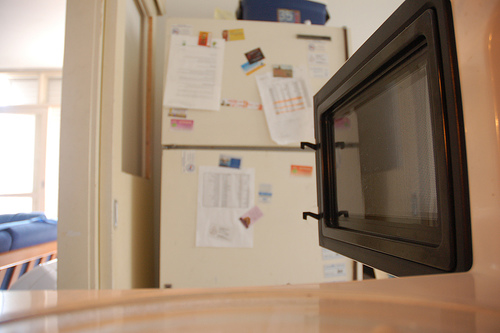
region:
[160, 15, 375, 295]
A refrigerator.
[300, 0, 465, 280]
The inside of the microwave door.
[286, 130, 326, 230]
Hooks that lock the door when it is closed.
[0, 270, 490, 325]
The glass dish.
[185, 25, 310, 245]
Various magnets are on the fridge.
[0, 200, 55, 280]
A couch.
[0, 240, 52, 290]
The couch has a wood frame.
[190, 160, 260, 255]
A piece of paper is attached to the fridge.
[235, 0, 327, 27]
A blue plastic tub.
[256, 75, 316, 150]
The paper has been highlighted.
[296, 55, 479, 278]
Black, opened door of the microwave.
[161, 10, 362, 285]
Beige colored refrigerator in the kitchen.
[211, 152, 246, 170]
Magnet on the refrigerator holding up a paper.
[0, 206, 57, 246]
Blue cushions on the couch.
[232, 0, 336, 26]
Object sitting on top of the fridge.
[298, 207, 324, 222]
Locking mechanism for the microwave door.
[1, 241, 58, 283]
Couch made of wood.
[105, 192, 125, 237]
Light switch on the wall.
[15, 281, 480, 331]
Round plate of the microwave for food to go on.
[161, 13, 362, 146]
Freezer portion of the refrigerator.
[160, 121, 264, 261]
paper on the refrigerator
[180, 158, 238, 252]
paper on the refrigerator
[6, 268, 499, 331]
the inside of the microwave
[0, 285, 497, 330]
the microwave tray in the microwave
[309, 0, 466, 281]
the door is open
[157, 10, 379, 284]
the refrigerator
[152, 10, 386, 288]
the refrigerator is beige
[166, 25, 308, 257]
the papers on the refrigerator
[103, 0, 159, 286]
the beige sliding door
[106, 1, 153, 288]
the sliding door is open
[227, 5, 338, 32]
the box on top of the refrigerator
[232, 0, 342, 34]
the box is blue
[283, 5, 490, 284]
Black microwave door is open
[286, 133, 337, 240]
Two prongs on microwave door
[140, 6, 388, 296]
A two door refridgerator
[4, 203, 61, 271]
Blue cushions on a couch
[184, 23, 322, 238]
Lots of magnets on refridgerator door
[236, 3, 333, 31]
A blue container on top of refridgerator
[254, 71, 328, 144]
A white paper with orange high lights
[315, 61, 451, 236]
Glass window on microwave door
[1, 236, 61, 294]
Wooden back to couch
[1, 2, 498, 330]
White insides of the microwave